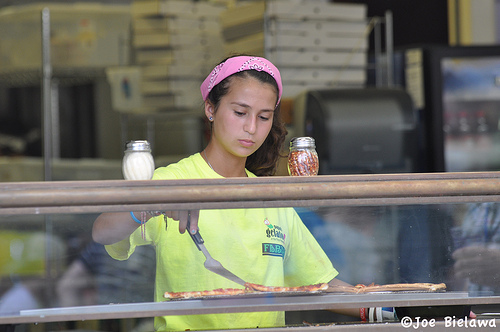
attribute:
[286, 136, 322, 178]
shaker — pepper, red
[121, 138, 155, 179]
jar — cheese, parmesan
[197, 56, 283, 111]
headband — pink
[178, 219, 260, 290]
spatula — black, triangular, metal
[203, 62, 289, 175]
hair — brunette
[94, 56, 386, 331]
girl — slicing, scooping, working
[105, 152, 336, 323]
shirt — yellow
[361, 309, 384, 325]
wristband — blue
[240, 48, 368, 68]
box — stacked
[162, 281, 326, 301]
pizza — warm